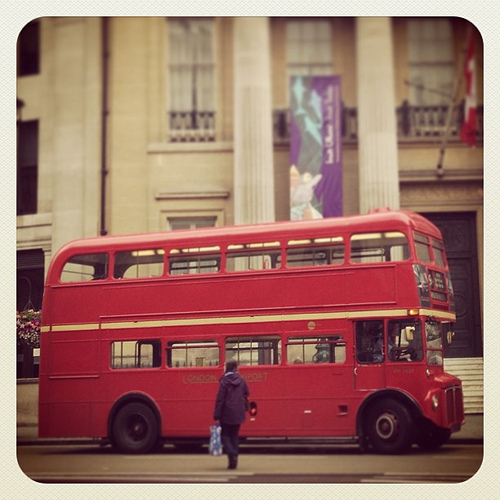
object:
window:
[166, 16, 217, 144]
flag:
[287, 77, 341, 219]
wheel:
[363, 394, 418, 455]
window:
[350, 231, 410, 265]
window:
[59, 252, 108, 283]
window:
[225, 242, 282, 275]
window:
[111, 339, 161, 369]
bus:
[37, 210, 465, 452]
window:
[114, 247, 166, 280]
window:
[169, 244, 220, 275]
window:
[285, 235, 345, 270]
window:
[167, 340, 219, 369]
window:
[225, 334, 282, 367]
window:
[287, 335, 347, 365]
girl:
[212, 359, 251, 471]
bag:
[209, 426, 223, 457]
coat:
[213, 371, 251, 426]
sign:
[428, 270, 445, 290]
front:
[400, 210, 465, 433]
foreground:
[12, 16, 487, 490]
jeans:
[221, 423, 241, 463]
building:
[15, 15, 485, 414]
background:
[19, 23, 489, 282]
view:
[40, 205, 468, 465]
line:
[39, 307, 457, 334]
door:
[354, 318, 387, 390]